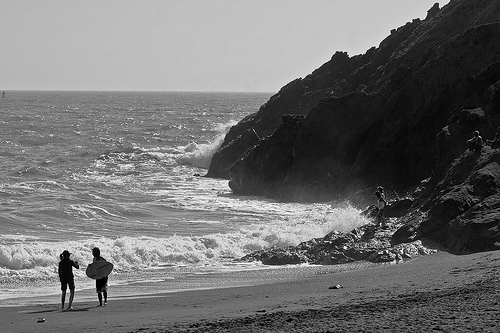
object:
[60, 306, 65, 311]
foot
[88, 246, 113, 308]
man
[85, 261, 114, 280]
board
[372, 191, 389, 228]
man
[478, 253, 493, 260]
tracks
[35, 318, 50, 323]
trash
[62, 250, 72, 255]
cap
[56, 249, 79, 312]
people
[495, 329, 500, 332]
sand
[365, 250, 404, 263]
rocks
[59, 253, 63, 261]
ponytail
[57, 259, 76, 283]
shirt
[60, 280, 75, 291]
pant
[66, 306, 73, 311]
foot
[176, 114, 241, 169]
waves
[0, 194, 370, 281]
waves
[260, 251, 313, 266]
rocks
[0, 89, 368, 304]
water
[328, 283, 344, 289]
trash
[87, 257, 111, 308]
body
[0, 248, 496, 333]
beach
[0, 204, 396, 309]
shore